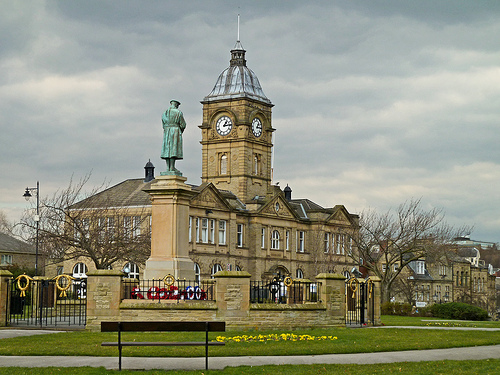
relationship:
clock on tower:
[250, 115, 264, 139] [200, 9, 275, 192]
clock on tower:
[211, 115, 232, 135] [200, 9, 275, 192]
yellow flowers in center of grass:
[236, 330, 342, 347] [0, 326, 497, 354]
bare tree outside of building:
[11, 170, 151, 280] [31, 12, 360, 300]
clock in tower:
[250, 115, 264, 139] [200, 9, 275, 192]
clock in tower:
[211, 115, 232, 135] [200, 9, 275, 192]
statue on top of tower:
[158, 98, 189, 175] [139, 175, 199, 299]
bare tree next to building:
[341, 197, 471, 312] [68, 17, 358, 307]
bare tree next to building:
[11, 170, 151, 280] [68, 17, 358, 307]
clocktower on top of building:
[201, 11, 274, 182] [62, 157, 368, 317]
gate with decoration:
[3, 273, 85, 330] [53, 273, 73, 299]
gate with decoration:
[3, 273, 85, 330] [13, 273, 31, 300]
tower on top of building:
[200, 9, 275, 192] [54, 16, 361, 333]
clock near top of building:
[250, 115, 264, 139] [68, 17, 358, 307]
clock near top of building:
[211, 115, 232, 135] [68, 17, 358, 307]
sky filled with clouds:
[16, 91, 126, 159] [2, 8, 497, 238]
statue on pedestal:
[158, 102, 189, 169] [143, 173, 188, 280]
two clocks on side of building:
[202, 109, 272, 145] [80, 107, 382, 319]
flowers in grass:
[210, 329, 339, 346] [260, 332, 427, 349]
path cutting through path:
[0, 343, 497, 369] [367, 325, 498, 332]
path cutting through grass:
[0, 343, 497, 369] [0, 326, 497, 354]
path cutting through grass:
[0, 343, 497, 369] [3, 357, 499, 373]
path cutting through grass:
[0, 343, 497, 369] [379, 314, 498, 327]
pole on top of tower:
[230, 9, 243, 49] [216, 89, 270, 161]